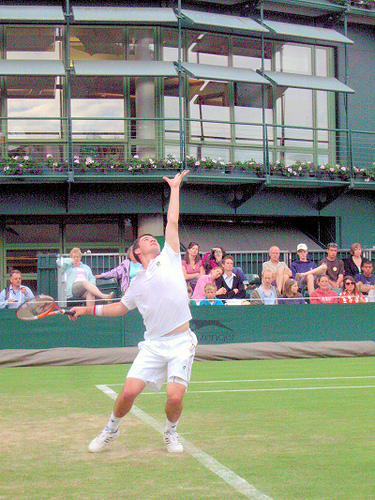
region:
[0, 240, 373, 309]
fans watching tennis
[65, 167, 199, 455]
person reaching toward sky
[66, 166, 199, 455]
person playing tennis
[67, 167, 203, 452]
player standing on green, grassy field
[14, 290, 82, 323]
tennis racket held by tennis player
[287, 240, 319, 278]
onlooker wearing white hat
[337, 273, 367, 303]
women in red and white shirt wearing sunglasses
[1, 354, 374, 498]
green field has white lines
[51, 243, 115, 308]
woman in blue cardigan has legs crossed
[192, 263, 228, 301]
woman in pink top leaning on a man in a blue top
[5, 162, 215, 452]
This is a tennis player.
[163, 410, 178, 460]
This is a white shoe.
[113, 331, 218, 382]
These are white shorts.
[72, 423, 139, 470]
This is the right shoe.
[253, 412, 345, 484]
This is grass.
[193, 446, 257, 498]
This is a white line.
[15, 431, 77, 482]
This is dead grass.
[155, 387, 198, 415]
This is a knee.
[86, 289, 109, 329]
This is a wrist band.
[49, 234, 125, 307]
This is a woman.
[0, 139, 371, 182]
Bed of flowers on balcony above audience.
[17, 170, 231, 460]
Man hitting the tennis ball.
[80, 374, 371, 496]
White boundary lines on tennis court.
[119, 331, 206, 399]
White shorts worn by tennis player.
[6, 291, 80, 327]
Tennis racket held by tennis player.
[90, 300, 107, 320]
Wrist band worn on arm of tennis player.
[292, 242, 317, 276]
Person wearing a white cap.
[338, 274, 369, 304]
Woman wearing sunglasses and red and white shirt.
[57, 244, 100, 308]
Older woman wearing shorts and light blue shirt.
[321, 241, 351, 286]
Man with the sunglasses on top of his head, next to person wearing white baseball cap.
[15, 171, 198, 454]
A man serving a tennis ball.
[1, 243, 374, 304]
A crowd of people watching a game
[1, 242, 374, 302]
People watching a tennis match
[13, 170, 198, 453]
A guy with a tennis racket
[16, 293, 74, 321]
A white and orange racket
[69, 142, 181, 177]
A windowsill with flowers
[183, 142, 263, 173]
A windowsill with flowers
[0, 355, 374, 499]
A grassy tennis court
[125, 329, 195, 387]
A pair of white shorts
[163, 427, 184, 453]
A white shoe with black stripes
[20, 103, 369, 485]
tennis is being played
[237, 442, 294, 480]
grass is green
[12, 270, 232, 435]
player is holding a raquet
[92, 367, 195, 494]
court lines are white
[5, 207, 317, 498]
it is a daytime scene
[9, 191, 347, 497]
it is an outdoor scene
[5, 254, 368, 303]
people are spectating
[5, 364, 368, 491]
this is a tennis court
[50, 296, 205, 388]
the player has a wrist band on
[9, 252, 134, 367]
the raquet is red in color